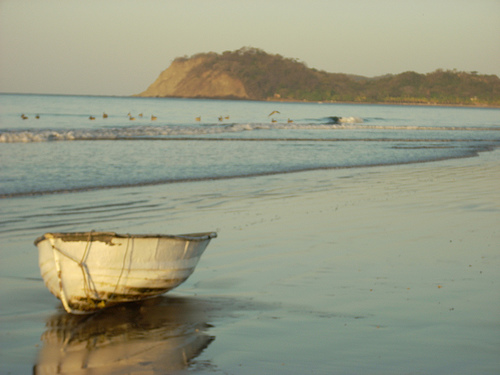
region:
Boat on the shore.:
[21, 186, 191, 357]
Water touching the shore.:
[161, 126, 372, 244]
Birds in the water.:
[86, 78, 408, 148]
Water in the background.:
[215, 112, 493, 217]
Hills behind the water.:
[128, 27, 488, 161]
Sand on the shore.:
[437, 141, 499, 329]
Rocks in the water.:
[98, 86, 396, 155]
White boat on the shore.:
[19, 204, 350, 347]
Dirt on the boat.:
[65, 279, 170, 332]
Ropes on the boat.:
[60, 209, 132, 293]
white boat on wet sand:
[35, 220, 223, 345]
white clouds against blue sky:
[12, 6, 70, 40]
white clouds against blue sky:
[3, 37, 53, 74]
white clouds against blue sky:
[23, 55, 84, 87]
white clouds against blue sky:
[81, 49, 123, 80]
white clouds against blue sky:
[112, 20, 193, 47]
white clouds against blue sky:
[223, 0, 287, 30]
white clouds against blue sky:
[296, 22, 366, 46]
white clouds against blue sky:
[378, 16, 443, 47]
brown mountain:
[226, 66, 273, 94]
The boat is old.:
[31, 224, 223, 314]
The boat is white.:
[27, 225, 220, 319]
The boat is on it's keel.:
[32, 223, 219, 313]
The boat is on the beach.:
[31, 223, 223, 318]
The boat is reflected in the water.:
[30, 308, 224, 373]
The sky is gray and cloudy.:
[1, 0, 499, 42]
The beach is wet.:
[233, 178, 495, 371]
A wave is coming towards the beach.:
[2, 120, 499, 147]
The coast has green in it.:
[130, 48, 497, 110]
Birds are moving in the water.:
[17, 107, 296, 126]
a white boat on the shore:
[47, 237, 79, 274]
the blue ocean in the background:
[202, 137, 226, 163]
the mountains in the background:
[217, 46, 264, 89]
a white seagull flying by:
[268, 107, 281, 117]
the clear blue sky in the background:
[309, 9, 349, 39]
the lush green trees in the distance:
[417, 88, 449, 98]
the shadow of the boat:
[132, 334, 177, 359]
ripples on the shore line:
[312, 164, 340, 200]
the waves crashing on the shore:
[54, 128, 71, 138]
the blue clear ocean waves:
[250, 148, 271, 170]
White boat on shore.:
[32, 229, 215, 313]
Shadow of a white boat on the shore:
[32, 312, 217, 374]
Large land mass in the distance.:
[137, 46, 498, 107]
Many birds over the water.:
[17, 108, 292, 127]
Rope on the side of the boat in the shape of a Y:
[42, 231, 96, 303]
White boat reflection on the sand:
[31, 305, 220, 374]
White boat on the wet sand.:
[31, 231, 220, 315]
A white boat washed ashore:
[31, 228, 216, 317]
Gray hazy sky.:
[0, 3, 496, 90]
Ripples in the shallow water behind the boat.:
[10, 193, 175, 233]